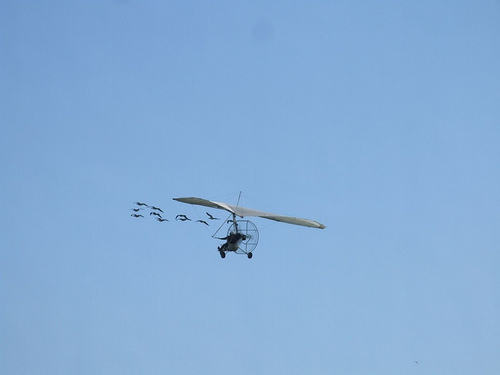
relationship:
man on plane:
[214, 231, 236, 251] [174, 190, 327, 258]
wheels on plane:
[219, 252, 254, 259] [174, 190, 327, 258]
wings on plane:
[173, 194, 327, 230] [174, 190, 327, 258]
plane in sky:
[174, 190, 327, 258] [0, 1, 500, 374]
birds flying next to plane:
[131, 200, 236, 226] [174, 190, 327, 258]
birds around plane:
[130, 199, 234, 224] [174, 190, 327, 258]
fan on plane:
[228, 220, 259, 255] [174, 190, 327, 258]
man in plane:
[214, 231, 236, 251] [174, 190, 327, 258]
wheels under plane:
[219, 252, 254, 259] [174, 190, 327, 258]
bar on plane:
[235, 190, 243, 208] [174, 190, 327, 258]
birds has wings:
[131, 200, 236, 226] [132, 200, 149, 208]